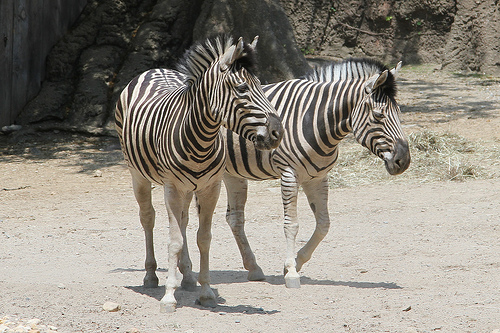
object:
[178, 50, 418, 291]
zebra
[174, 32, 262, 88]
mane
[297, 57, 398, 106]
mane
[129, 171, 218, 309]
legs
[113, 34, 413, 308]
zebras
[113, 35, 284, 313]
zebra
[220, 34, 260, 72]
ear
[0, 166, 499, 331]
dirt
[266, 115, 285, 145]
nose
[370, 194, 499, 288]
dirt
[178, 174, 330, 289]
leg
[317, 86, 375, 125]
wall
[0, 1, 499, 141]
boulder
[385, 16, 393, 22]
greenery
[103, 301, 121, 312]
rock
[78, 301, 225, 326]
dirt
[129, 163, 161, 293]
leg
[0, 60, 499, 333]
ground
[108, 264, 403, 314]
shadow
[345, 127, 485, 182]
bush